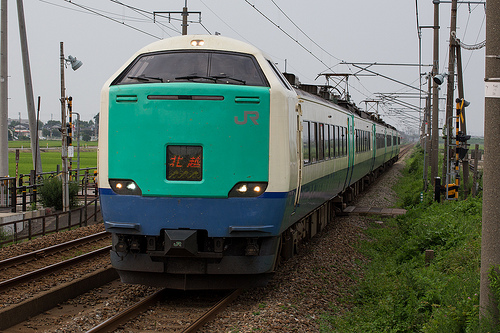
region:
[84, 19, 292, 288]
the front of a train car.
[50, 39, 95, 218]
a light on train tracks.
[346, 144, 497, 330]
green grass near train tracks.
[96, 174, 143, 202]
headlight on a train.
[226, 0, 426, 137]
powerlines near train tracks.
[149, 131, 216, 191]
the very front of a train.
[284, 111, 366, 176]
windows on the side of a train.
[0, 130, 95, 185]
a field of green grass.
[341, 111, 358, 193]
a door on a train.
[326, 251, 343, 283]
a section of ground near a train..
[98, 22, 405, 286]
the train on the track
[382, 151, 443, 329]
the grass near the train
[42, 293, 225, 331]
the train tracks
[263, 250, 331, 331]
the rocks near the train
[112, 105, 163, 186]
the green on the train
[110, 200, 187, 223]
the blue on the train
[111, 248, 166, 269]
the black on the train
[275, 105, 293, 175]
the white on the train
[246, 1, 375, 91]
the power lines in the sky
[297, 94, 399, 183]
the windows on the side of the train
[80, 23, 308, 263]
front of train in tracks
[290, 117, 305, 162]
window on side of train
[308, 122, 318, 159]
window on side of train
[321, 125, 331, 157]
window on side of train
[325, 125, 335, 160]
window on side of train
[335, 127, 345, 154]
window on side of train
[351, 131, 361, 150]
window on side of train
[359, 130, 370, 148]
window on side of train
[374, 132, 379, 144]
window on side of train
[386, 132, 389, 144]
window on side of train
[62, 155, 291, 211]
the headlights are on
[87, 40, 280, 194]
the front of the train is green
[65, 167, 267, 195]
there are 4 lights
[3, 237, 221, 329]
there are two tracks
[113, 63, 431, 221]
the train has 6 cars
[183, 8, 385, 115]
there are wires above the train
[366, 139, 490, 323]
wild grass is growing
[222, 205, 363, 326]
the gravel is brown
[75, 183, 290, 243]
there is a blue panel under the headlights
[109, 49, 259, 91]
the windows are black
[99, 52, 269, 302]
front of train on tracks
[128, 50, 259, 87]
window on green train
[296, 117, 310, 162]
window on green train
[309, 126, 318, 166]
window on green train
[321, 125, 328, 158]
window on green train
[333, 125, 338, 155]
window on green train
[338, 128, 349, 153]
window on green train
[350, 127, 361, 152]
window on green train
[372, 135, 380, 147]
window on green train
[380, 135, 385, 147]
window on green train